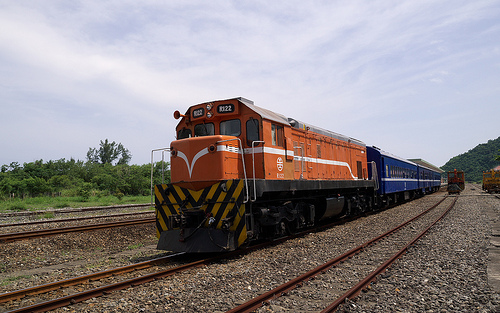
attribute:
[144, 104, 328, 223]
train — orange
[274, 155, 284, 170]
logo — white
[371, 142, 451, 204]
train car — blue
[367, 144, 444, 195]
train cars — blue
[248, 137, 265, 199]
railing — white, hand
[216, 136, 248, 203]
railing — white, hand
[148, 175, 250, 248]
black lines — yellow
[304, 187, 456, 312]
rail — long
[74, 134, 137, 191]
tree — tall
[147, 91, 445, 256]
train — white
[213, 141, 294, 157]
line — white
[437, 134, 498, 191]
mountains — hills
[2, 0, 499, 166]
sky — blue, white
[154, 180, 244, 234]
stripes — black, yellow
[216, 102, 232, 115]
number — black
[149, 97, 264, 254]
front — orange